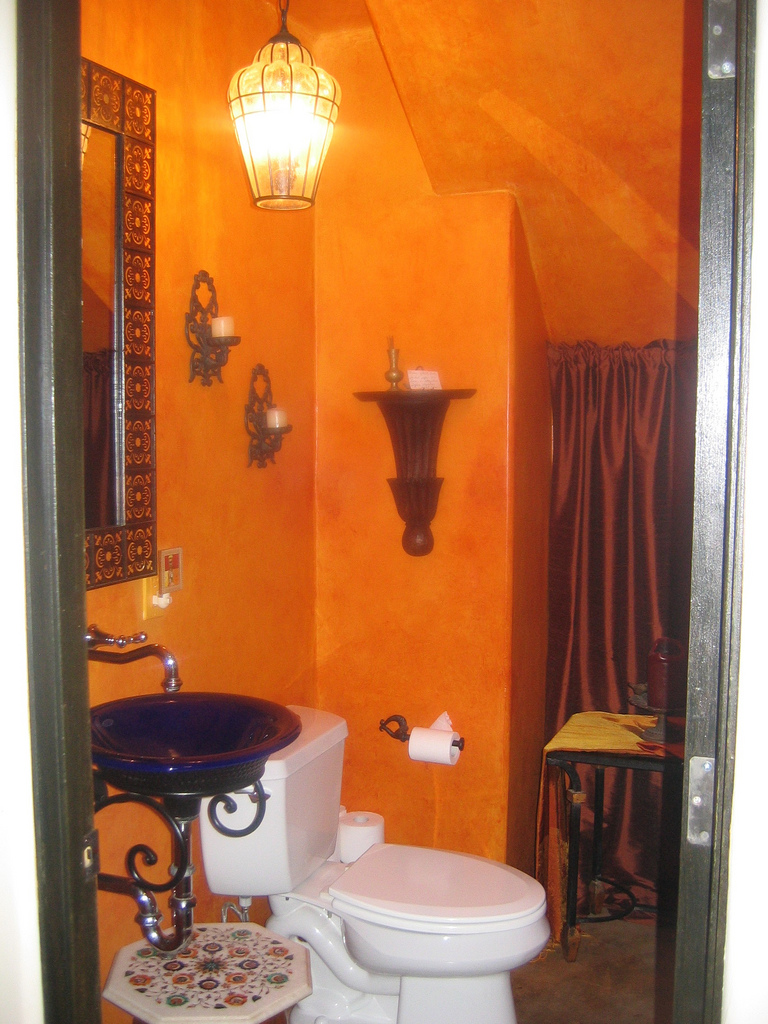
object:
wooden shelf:
[353, 388, 477, 550]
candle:
[207, 312, 234, 340]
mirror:
[89, 134, 119, 520]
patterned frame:
[124, 79, 157, 578]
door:
[578, 5, 717, 1010]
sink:
[77, 674, 310, 877]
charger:
[135, 547, 195, 619]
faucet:
[83, 616, 188, 703]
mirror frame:
[76, 68, 163, 594]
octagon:
[188, 978, 215, 1000]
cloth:
[564, 662, 657, 783]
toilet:
[388, 718, 468, 798]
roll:
[403, 722, 461, 776]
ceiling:
[281, 0, 697, 350]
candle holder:
[183, 265, 247, 393]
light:
[219, 3, 347, 220]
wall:
[116, 14, 560, 857]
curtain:
[546, 328, 691, 931]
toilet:
[188, 696, 559, 1019]